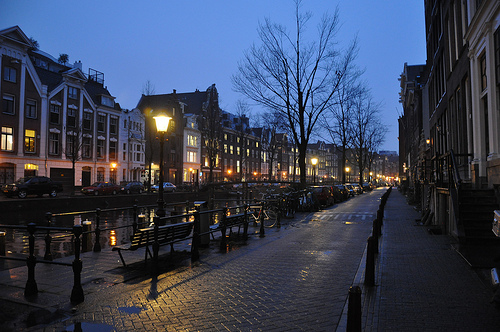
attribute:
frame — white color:
[467, 20, 498, 165]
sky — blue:
[2, 1, 427, 157]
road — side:
[84, 183, 391, 328]